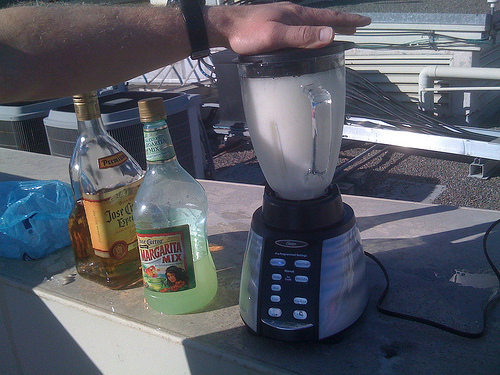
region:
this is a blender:
[211, 22, 396, 339]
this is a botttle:
[116, 102, 243, 342]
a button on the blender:
[289, 256, 316, 280]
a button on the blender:
[263, 280, 288, 300]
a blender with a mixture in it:
[236, 47, 373, 342]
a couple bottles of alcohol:
[72, 87, 223, 331]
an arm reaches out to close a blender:
[0, 4, 371, 104]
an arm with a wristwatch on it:
[2, 0, 367, 91]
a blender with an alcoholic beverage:
[223, 33, 381, 353]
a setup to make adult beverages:
[0, 40, 401, 341]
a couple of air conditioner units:
[0, 71, 231, 178]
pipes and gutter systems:
[396, 31, 498, 178]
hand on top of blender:
[0, 3, 372, 346]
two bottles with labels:
[66, 92, 218, 313]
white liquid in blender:
[236, 40, 348, 197]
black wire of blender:
[365, 219, 497, 339]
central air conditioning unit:
[42, 88, 208, 180]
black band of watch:
[169, 0, 209, 60]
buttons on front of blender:
[267, 255, 309, 320]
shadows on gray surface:
[179, 204, 499, 374]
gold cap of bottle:
[137, 96, 164, 124]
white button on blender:
[268, 256, 287, 269]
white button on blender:
[293, 258, 310, 270]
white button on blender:
[271, 271, 283, 282]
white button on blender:
[269, 281, 284, 292]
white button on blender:
[270, 293, 282, 303]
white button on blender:
[292, 295, 309, 308]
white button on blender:
[266, 306, 283, 318]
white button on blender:
[292, 310, 309, 322]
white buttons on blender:
[261, 257, 286, 319]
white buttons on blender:
[291, 297, 306, 322]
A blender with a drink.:
[229, 55, 381, 342]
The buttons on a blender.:
[267, 250, 321, 322]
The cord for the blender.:
[364, 217, 494, 340]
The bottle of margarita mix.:
[111, 96, 214, 318]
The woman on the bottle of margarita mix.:
[160, 263, 195, 291]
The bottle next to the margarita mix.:
[61, 92, 141, 286]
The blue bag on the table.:
[1, 165, 70, 269]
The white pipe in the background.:
[413, 55, 498, 112]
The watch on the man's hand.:
[175, 0, 222, 64]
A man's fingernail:
[318, 21, 342, 49]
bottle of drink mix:
[133, 95, 218, 316]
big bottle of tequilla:
[67, 91, 145, 291]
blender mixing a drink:
[237, 38, 368, 345]